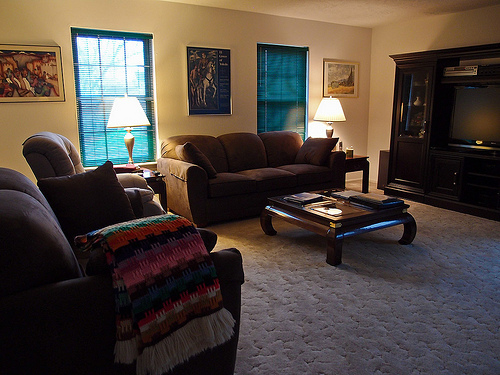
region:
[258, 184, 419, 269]
square coffee table stacked with magazines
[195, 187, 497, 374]
beige hi-low carpeting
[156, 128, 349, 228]
burnished brown leather couch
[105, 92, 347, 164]
two matching lamps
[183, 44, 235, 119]
framed artwork of a rider and horse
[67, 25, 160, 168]
blue mini blinds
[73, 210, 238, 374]
brightly colored fringed afghan blanket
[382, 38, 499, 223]
wall sized entertainment cabinet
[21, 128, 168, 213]
beige recliner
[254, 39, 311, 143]
closed mini blinds shutting out light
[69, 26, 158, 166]
Window with shades open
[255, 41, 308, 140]
Window with shades shut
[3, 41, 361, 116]
Three framed pieces of artwork on a wall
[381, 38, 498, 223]
Large dark wood tv stand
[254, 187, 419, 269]
Dark wood square shaped coffee table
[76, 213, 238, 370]
Quilted blanket hanging on arm of sofa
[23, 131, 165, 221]
Single person reclining sofa chair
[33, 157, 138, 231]
Throw pillow on sofa chair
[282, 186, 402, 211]
Several books on a coffee table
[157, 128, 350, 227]
Long three person sofa couch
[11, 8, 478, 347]
the inside of a livingroom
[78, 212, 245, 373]
a colorful afghan blanket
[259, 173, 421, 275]
a wooden coffee table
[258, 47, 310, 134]
a window with the blinds closed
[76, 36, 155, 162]
a window with the blinds open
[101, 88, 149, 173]
a lamp on a table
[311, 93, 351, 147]
a lamp on a table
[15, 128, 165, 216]
a leather recliner chair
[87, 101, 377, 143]
two white lampshades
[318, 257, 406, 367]
carpet is light brown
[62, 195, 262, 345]
colorful afghan on sofa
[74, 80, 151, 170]
blue blinds on window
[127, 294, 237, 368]
grey fringe on afghan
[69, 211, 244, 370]
BLANKET OVER ARM OF CHAIR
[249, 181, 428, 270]
COFFEE TABLE IN FRONT OF SOFA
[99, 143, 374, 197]
END TABLES ON BOTH SIDES OF SOFA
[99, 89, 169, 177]
LAMP ON END TABLE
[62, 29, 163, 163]
HORIZONTAL BLINDS ON WINDOW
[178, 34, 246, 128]
PICTURE WITH A HORSE ON WALL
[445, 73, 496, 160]
TELEVISION BUILT INTO CABINET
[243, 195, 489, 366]
FLOOR IS COVERED IN CARPET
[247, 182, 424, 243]
COFFEE TABLE IS SQUARE IN SHAPE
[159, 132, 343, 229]
large brown cloth couch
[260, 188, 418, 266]
large wooden brown table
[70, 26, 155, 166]
large tall glass window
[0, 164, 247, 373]
large brown cloth couch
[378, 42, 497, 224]
large tall wooden brown cabinet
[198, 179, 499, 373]
large open grey carpet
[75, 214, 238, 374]
large folded multi colored blanket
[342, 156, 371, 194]
small short wooden end table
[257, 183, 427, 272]
square end table by couch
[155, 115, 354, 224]
brown couch against wall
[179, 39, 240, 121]
picture on wall above couch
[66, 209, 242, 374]
folded blanket on chair arm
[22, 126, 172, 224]
recliner by end table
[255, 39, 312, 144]
blue blinds hanging in window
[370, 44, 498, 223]
large entertainment center by wall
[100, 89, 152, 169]
lamp on end table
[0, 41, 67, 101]
painting to left of window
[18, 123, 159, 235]
A chair in a living room.